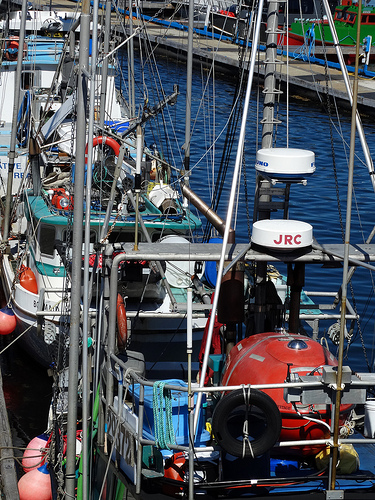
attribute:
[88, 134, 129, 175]
life wheel — red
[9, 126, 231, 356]
boat — green, white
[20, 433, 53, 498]
buoys — red, plastic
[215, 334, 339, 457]
engine — large, red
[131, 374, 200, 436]
tub — blue, plastic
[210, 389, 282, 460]
tire — black, round 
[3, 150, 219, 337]
boat — turqoise, white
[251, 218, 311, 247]
disk — white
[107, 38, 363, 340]
water — dark blue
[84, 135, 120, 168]
lifesaver — orange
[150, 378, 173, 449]
rope — blue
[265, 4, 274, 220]
mast — tall, silver, metal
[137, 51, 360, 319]
water — dark blue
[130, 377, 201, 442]
container — blue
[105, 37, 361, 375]
water — blue, crystal clear 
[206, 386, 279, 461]
tire — black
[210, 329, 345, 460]
ball — large, round, red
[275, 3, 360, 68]
boat — red, green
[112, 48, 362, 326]
water — dark blue, dark, blue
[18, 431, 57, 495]
bouys — red, faded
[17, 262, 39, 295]
tank — red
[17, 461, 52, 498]
boat anchor — orange 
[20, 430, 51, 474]
boat anchor — orange 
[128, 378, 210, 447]
bin — blue , plastic 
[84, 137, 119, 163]
life preserver — orange 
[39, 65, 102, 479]
chain — grey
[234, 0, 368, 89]
boat — green, red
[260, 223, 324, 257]
letters — red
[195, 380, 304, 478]
tire — black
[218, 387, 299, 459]
tire — black